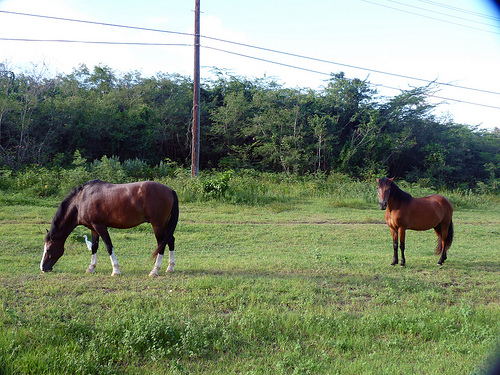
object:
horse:
[37, 178, 182, 279]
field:
[7, 83, 499, 369]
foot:
[109, 268, 124, 277]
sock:
[105, 251, 124, 278]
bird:
[82, 234, 98, 251]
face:
[38, 237, 66, 273]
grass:
[13, 297, 496, 374]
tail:
[151, 187, 179, 260]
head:
[37, 229, 68, 272]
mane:
[44, 184, 84, 237]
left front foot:
[102, 221, 122, 279]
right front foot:
[81, 215, 101, 273]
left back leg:
[147, 217, 166, 280]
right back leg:
[164, 226, 178, 276]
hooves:
[82, 245, 178, 280]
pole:
[186, 0, 203, 180]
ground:
[16, 215, 494, 304]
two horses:
[37, 162, 458, 277]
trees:
[1, 69, 497, 178]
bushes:
[0, 166, 499, 205]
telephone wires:
[8, 16, 497, 106]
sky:
[1, 0, 500, 122]